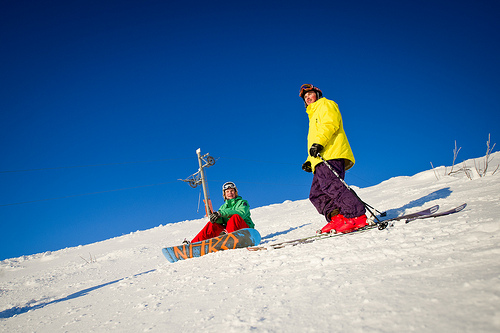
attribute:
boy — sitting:
[182, 182, 255, 243]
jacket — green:
[218, 197, 253, 228]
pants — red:
[192, 215, 249, 244]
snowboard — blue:
[163, 228, 261, 263]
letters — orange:
[173, 234, 239, 263]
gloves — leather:
[207, 209, 222, 224]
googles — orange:
[299, 84, 313, 100]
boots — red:
[321, 214, 367, 233]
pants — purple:
[309, 159, 366, 215]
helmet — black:
[315, 87, 322, 101]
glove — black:
[310, 144, 321, 157]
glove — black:
[301, 158, 312, 172]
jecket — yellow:
[308, 98, 355, 170]